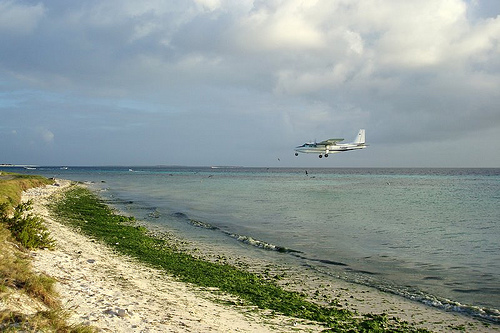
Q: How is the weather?
A: Sunny.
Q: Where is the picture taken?
A: A beach.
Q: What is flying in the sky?
A: A plane.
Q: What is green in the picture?
A: Grass.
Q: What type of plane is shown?
A: Single engine.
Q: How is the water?
A: Calm.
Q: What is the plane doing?
A: Landing.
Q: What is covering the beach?
A: Sand.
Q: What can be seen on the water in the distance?
A: Boats.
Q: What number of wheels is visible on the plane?
A: 3.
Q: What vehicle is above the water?
A: A plane.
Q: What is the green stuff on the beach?
A: Grass.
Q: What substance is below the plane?
A: Water.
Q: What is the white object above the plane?
A: A cloud.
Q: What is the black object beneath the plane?
A: A wheel.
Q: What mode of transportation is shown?
A: Plane.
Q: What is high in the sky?
A: Clouds.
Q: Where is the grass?
A: On the shore.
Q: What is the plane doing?
A: Flying.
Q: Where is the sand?
A: Beside the grass.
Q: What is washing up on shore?
A: Waves.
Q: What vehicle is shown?
A: Aircraft.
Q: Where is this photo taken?
A: Beach.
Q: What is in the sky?
A: Clouds.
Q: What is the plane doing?
A: Landing.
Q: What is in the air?
A: Small plane.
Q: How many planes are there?
A: One.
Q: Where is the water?
A: Below plane.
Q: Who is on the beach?
A: No one.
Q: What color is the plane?
A: White.